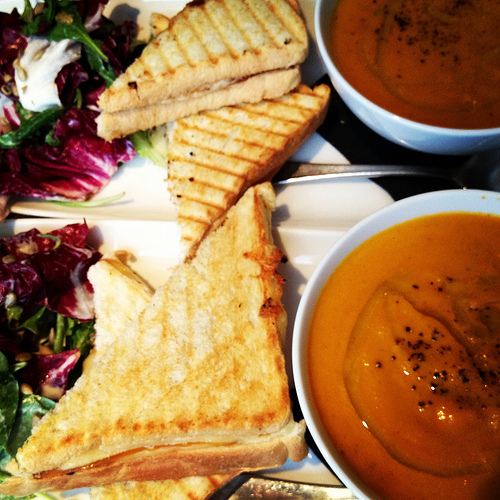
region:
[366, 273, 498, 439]
black condiment in the soup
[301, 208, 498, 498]
the soup is orange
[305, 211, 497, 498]
soup is in a bowl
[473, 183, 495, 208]
soup stains on bowl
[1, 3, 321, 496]
bread next to bowl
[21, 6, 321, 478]
lines on the bread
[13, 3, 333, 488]
the bread is toasted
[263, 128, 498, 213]
spoon next to the bowls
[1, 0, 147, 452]
red lettuce next to bread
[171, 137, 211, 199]
brown spots on bread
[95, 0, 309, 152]
Grilled sandiwch cut crossways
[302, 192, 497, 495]
Red sauce in white bowl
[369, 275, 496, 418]
Black pepper in midst of sauce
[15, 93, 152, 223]
Purple vegetable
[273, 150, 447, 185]
Silverware on plate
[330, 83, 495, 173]
White bowl of sauce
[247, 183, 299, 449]
Crust of the bread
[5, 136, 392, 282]
White platters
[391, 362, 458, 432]
Reflection of light in the sauce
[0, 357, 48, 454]
Green leaves next to sandwiches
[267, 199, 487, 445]
white bowl with food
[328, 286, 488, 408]
orange food in bowl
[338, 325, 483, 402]
black pepper on top of food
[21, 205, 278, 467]
grill marks on top of bread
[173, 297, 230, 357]
white and orange grill marks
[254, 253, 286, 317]
melted cheese on outside of bread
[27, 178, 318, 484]
grilled cheese sandwich on plate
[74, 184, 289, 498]
grilled cheese cut into triangles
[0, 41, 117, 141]
small salad on side of plate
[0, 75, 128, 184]
red cabbage in salad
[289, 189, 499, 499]
A bowl of soup.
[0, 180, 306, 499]
A toasted cheese sandwich.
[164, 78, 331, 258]
A grilled cheese sandwich.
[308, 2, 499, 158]
A bowl of tomato soup.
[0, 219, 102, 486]
Green and purple salad.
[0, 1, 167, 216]
Salad on a plate.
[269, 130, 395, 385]
A white dinner plate.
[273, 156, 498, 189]
A silver eating utensil.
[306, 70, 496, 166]
A dark colored tabletop.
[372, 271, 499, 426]
Spices on tomato soup.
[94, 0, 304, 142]
half of a sandwich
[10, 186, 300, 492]
sandwich in a triangle shape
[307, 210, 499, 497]
the soup is orange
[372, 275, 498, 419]
seasoning on the soup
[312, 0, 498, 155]
a bowl of soup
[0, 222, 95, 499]
green and red salad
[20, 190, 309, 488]
the bread is toasted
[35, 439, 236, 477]
cheese in the sandwich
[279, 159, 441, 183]
the utensil is silver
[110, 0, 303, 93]
grill marks on bread